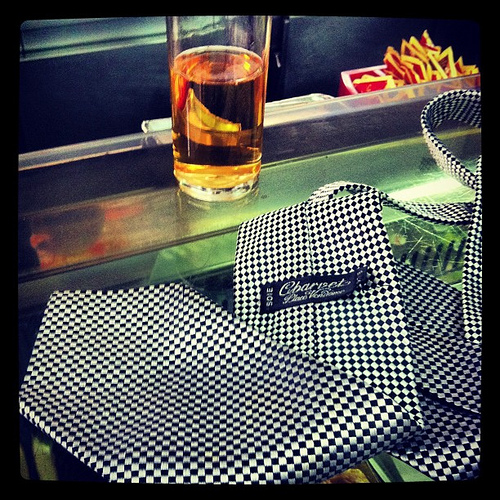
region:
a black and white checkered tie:
[30, 196, 434, 476]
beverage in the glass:
[159, 14, 302, 228]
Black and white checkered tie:
[17, 77, 499, 499]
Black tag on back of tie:
[254, 268, 375, 317]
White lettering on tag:
[259, 266, 362, 326]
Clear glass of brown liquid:
[162, 0, 274, 229]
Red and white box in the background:
[314, 13, 499, 140]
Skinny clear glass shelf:
[22, 120, 499, 271]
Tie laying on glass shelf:
[14, 86, 496, 488]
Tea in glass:
[169, 30, 274, 205]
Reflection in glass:
[17, 127, 229, 324]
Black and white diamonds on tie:
[39, 273, 352, 499]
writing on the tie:
[260, 265, 362, 317]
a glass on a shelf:
[160, 11, 270, 211]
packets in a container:
[345, 35, 470, 100]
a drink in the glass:
[156, 15, 278, 200]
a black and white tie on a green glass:
[25, 80, 490, 490]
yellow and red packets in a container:
[341, 28, 480, 115]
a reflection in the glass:
[35, 211, 227, 277]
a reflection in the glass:
[178, 49, 263, 188]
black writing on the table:
[403, 239, 473, 280]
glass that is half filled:
[153, 13, 269, 216]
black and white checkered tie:
[15, 115, 485, 477]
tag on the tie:
[241, 260, 372, 310]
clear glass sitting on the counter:
[160, 15, 277, 217]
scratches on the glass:
[396, 210, 471, 265]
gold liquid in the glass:
[166, 50, 267, 195]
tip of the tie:
[37, 281, 82, 311]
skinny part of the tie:
[325, 170, 465, 230]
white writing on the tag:
[277, 272, 353, 292]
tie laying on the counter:
[13, 85, 484, 483]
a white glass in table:
[150, 52, 310, 222]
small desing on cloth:
[168, 370, 265, 456]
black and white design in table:
[94, 359, 308, 483]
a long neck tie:
[243, 178, 425, 463]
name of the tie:
[247, 270, 372, 312]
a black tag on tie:
[222, 253, 373, 318]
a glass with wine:
[169, 40, 299, 245]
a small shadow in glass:
[186, 86, 258, 133]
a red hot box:
[345, 18, 494, 117]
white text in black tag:
[272, 262, 375, 322]